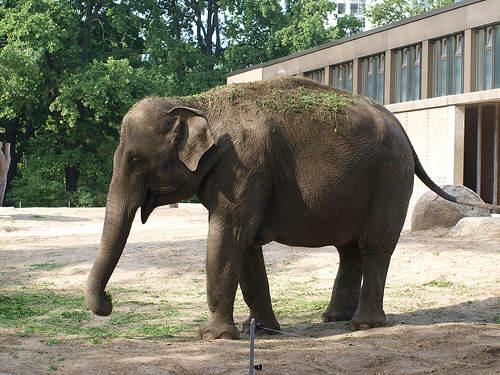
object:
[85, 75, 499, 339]
elephant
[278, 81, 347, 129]
grass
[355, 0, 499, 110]
building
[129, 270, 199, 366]
dirt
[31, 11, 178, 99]
trees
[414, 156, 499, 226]
tail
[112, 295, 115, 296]
hay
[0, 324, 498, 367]
mound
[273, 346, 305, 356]
hay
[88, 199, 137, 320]
trunk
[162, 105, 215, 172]
ear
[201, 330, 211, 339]
toe nail